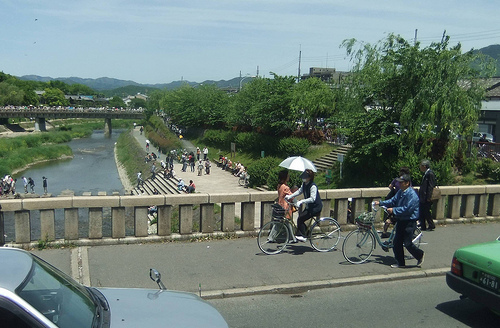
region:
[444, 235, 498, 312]
green car on bridge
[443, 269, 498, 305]
black bumper on green car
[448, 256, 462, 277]
red tail light on car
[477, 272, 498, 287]
white license plate on car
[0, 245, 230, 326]
silver car on bridge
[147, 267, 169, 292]
side mirror attached to the silver car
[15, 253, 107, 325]
windshield on silver car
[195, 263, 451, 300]
curb next to car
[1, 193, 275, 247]
concrete safety railing on bridge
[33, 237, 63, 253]
weeds growing next to safety railing on bridge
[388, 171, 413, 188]
Man wearing a black cap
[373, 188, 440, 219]
Man wearing blue jacket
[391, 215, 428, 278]
Man wearing black pants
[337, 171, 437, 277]
Man pushing his bike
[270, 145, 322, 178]
Woman carrying an umbrella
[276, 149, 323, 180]
Umbrella is blue and white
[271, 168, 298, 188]
Woman has dark hair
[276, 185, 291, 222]
Woman wearing pink dress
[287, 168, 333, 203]
Woman wearing dark shirt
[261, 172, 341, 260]
Woman riding her bike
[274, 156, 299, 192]
Lady walking with blue & white umbrella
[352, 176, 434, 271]
Man walking beside a bicycle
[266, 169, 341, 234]
person riding a bicycle over a bridge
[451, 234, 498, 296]
green car on a bridge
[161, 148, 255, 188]
Crowd of people standing on a landing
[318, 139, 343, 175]
stairs leading down to a river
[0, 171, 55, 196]
people walking on stones across a river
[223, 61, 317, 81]
power poles rising above trees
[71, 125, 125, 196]
narrow river flowing through a city area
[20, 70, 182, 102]
mountain landscape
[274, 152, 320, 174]
a silver umbrella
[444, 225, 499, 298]
the trunk of a green car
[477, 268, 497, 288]
a license plate on a car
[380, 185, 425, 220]
a blue shirt on a man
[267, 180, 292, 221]
an orange dress on a woman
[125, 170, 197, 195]
concrete steps going down to the water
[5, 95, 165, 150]
a bridge over the water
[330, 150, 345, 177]
a sign on a post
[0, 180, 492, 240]
a concrete railing along a sidewalk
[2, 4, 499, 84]
a pale blue sky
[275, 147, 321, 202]
A white and blue umbrella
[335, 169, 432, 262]
A man in a blue jacket walking a bike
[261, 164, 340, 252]
A woman wearing white sleeves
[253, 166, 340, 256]
A woman in black and white riding a bike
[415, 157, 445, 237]
A man in a black suit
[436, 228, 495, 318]
The back of a green car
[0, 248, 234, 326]
The front of a silver car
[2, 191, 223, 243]
Concrete bridge railing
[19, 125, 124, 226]
A river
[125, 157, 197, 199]
People on concrete stairs